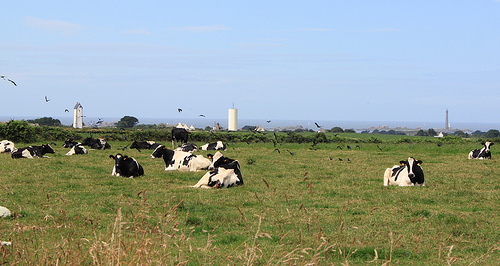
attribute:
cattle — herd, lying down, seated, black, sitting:
[19, 127, 500, 196]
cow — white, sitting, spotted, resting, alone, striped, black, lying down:
[370, 147, 432, 201]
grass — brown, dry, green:
[255, 150, 360, 265]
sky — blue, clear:
[93, 27, 399, 75]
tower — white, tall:
[219, 107, 248, 135]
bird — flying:
[33, 88, 53, 103]